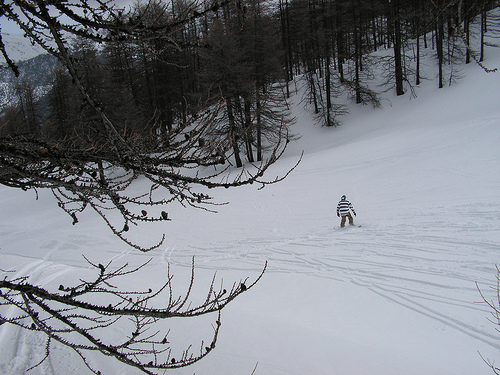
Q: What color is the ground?
A: White.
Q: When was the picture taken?
A: In the daytime.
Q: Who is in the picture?
A: A snowboarder.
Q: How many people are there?
A: 1.